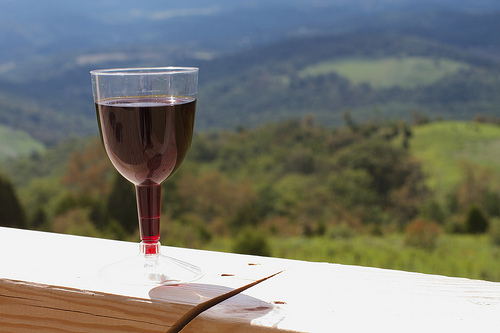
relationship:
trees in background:
[0, 0, 499, 258] [0, 0, 499, 282]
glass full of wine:
[90, 66, 204, 286] [95, 98, 195, 256]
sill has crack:
[0, 225, 499, 332] [167, 270, 284, 332]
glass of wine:
[90, 66, 204, 286] [95, 98, 195, 256]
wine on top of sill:
[95, 98, 195, 256] [0, 225, 499, 332]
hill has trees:
[0, 121, 499, 235] [0, 0, 499, 258]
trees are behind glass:
[0, 0, 499, 258] [90, 66, 204, 286]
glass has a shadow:
[90, 66, 204, 286] [148, 283, 273, 321]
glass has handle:
[90, 66, 204, 286] [134, 185, 161, 255]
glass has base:
[90, 66, 204, 286] [109, 254, 203, 287]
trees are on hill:
[0, 0, 499, 258] [0, 121, 499, 235]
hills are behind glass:
[0, 0, 499, 282] [90, 66, 204, 286]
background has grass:
[0, 0, 499, 282] [0, 0, 499, 282]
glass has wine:
[90, 66, 204, 286] [95, 98, 195, 256]